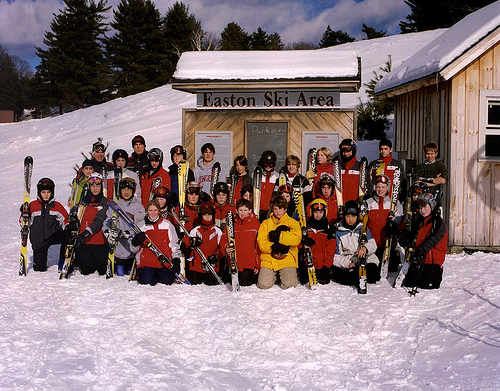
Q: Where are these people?
A: At a ski resort.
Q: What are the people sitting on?
A: The ground.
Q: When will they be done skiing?
A: Nighttime.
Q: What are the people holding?
A: Ski supplies.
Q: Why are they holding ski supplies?
A: There is snow on the ground.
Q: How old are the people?
A: Under 20.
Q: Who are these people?
A: Children.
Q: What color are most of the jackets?
A: Red.